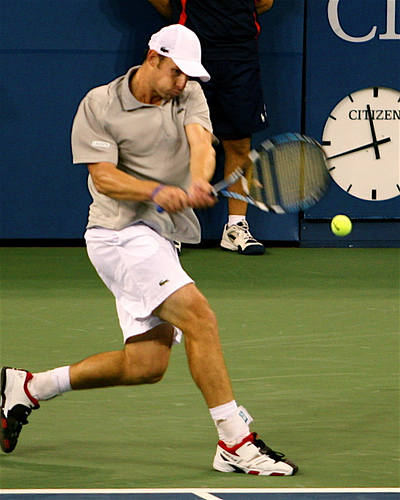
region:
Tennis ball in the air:
[326, 215, 365, 241]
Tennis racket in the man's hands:
[149, 125, 347, 213]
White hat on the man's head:
[97, 10, 232, 91]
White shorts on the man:
[76, 211, 223, 344]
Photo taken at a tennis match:
[17, 3, 394, 491]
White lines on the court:
[1, 474, 397, 494]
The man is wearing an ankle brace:
[214, 397, 279, 457]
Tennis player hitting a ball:
[26, 12, 342, 480]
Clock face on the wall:
[307, 33, 399, 215]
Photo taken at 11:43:
[317, 83, 393, 239]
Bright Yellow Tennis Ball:
[324, 213, 355, 239]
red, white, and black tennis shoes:
[212, 436, 301, 479]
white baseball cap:
[143, 18, 216, 81]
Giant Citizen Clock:
[316, 80, 396, 206]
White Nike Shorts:
[79, 231, 197, 315]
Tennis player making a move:
[29, 9, 323, 489]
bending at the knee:
[96, 331, 176, 401]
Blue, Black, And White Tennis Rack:
[212, 125, 333, 223]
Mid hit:
[57, 126, 360, 223]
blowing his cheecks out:
[139, 44, 204, 109]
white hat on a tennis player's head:
[144, 21, 211, 80]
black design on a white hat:
[155, 41, 172, 55]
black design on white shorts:
[150, 276, 176, 287]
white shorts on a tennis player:
[83, 223, 197, 344]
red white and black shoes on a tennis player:
[208, 431, 304, 477]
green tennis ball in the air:
[325, 212, 353, 237]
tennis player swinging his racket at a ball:
[0, 22, 358, 476]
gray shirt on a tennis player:
[69, 67, 216, 246]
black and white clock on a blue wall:
[316, 81, 398, 205]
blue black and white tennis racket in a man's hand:
[153, 131, 334, 220]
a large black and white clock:
[321, 89, 399, 199]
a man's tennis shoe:
[209, 440, 300, 477]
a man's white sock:
[207, 398, 246, 441]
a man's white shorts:
[78, 225, 195, 345]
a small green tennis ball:
[328, 212, 352, 236]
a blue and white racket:
[153, 131, 331, 215]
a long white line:
[2, 480, 399, 497]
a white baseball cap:
[145, 23, 219, 84]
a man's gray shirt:
[71, 64, 216, 246]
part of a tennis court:
[0, 248, 398, 486]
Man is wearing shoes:
[2, 363, 300, 477]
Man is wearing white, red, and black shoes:
[0, 363, 304, 478]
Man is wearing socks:
[25, 363, 258, 448]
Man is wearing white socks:
[23, 361, 254, 447]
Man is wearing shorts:
[78, 224, 204, 342]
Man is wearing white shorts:
[78, 223, 199, 340]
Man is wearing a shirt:
[64, 65, 214, 251]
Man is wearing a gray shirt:
[66, 65, 216, 251]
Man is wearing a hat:
[146, 21, 212, 82]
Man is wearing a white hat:
[142, 20, 212, 85]